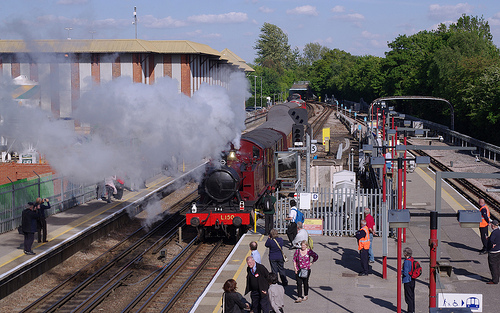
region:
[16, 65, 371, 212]
SMOKE COMING OUT THE THE TRAIN ENGINE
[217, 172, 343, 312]
PEOPLE STANDING NEAR THE TRAIN TRACKS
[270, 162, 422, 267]
FENCING NEAR THE TRAIN TRACK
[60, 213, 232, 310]
TRAIN TRACKS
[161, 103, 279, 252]
BLACK AND READ TRAIN ENGINE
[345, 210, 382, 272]
MAN STANDING IN A ORANGE SAFETY VEST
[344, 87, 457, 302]
RED PAINTED LIGHT POLE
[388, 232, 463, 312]
MAN STANDING WITH A RED BACKPACK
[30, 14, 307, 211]
BUILDING NEAR THE TRAIN TRACKS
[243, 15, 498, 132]
TREES NEAR THE TRAIN TRACKS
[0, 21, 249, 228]
gray smoke coming out of train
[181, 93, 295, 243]
train is a steam train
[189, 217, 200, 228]
round metal bumpers on front of train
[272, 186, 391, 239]
gray fence on platform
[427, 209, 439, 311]
red metal pole with a black top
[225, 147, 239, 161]
gold bell on train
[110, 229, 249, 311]
train on a tack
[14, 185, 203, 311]
track next to track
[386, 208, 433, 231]
light on metal pole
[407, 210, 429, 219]
black arm on pole supporting light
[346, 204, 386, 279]
man wearing an orange vest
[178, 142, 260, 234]
black train on the track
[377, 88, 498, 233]
empty train track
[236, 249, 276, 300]
man wearing a business suit with a blue collar shirt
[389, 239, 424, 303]
man wearing blue shirt with red backpack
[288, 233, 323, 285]
woman wearing purple shirt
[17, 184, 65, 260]
two men dressed in black business suit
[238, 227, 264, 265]
man wearing blue shirt with balding head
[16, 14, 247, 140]
brick building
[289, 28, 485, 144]
green luscious trees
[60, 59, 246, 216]
billowing white smoke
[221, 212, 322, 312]
people at a train station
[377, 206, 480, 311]
light post at the train station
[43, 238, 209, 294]
metal railroad tracks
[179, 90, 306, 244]
red and black train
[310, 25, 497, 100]
tall green trees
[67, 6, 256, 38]
a sky filled with clouds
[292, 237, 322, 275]
a woman wearing a purple shirt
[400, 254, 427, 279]
a red backpack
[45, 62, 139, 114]
brown and white stripes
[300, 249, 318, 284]
Person wearing purple printed shirt.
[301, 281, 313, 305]
Person wearing black pants.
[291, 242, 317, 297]
Bag around person's shoulder.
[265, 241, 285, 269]
Person wearing blue shirt.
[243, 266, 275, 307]
Person wearing black suit.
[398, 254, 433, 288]
Red backpack on person's back.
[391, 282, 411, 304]
Person wearing black pants.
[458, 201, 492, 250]
Person wearing orange vest.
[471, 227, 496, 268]
Person wearing black pants.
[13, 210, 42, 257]
Person wearing dark clothing.